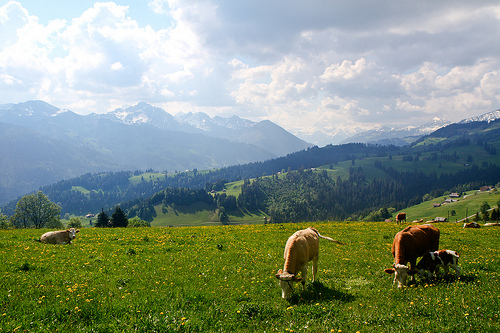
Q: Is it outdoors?
A: Yes, it is outdoors.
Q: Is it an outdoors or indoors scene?
A: It is outdoors.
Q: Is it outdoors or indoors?
A: It is outdoors.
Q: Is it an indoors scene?
A: No, it is outdoors.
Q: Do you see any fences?
A: No, there are no fences.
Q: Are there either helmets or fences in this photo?
A: No, there are no fences or helmets.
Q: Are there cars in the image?
A: No, there are no cars.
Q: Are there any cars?
A: No, there are no cars.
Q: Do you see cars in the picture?
A: No, there are no cars.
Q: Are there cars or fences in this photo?
A: No, there are no cars or fences.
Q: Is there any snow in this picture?
A: Yes, there is snow.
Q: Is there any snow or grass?
A: Yes, there is snow.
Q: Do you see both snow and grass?
A: Yes, there are both snow and grass.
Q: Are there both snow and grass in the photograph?
A: Yes, there are both snow and grass.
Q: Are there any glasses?
A: No, there are no glasses.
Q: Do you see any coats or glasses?
A: No, there are no glasses or coats.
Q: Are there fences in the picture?
A: No, there are no fences.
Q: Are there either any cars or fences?
A: No, there are no fences or cars.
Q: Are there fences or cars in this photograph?
A: No, there are no fences or cars.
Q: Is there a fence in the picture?
A: No, there are no fences.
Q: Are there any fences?
A: No, there are no fences.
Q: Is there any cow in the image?
A: Yes, there is a cow.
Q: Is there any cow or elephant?
A: Yes, there is a cow.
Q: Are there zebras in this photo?
A: No, there are no zebras.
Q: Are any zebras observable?
A: No, there are no zebras.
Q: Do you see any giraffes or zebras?
A: No, there are no zebras or giraffes.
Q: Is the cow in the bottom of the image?
A: Yes, the cow is in the bottom of the image.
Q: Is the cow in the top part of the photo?
A: No, the cow is in the bottom of the image.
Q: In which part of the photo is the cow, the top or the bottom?
A: The cow is in the bottom of the image.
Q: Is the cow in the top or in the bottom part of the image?
A: The cow is in the bottom of the image.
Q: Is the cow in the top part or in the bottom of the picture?
A: The cow is in the bottom of the image.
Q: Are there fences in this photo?
A: No, there are no fences.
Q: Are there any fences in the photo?
A: No, there are no fences.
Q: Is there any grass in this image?
A: Yes, there is grass.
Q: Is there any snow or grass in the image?
A: Yes, there is grass.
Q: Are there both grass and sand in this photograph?
A: No, there is grass but no sand.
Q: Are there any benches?
A: No, there are no benches.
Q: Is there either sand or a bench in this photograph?
A: No, there are no benches or sand.